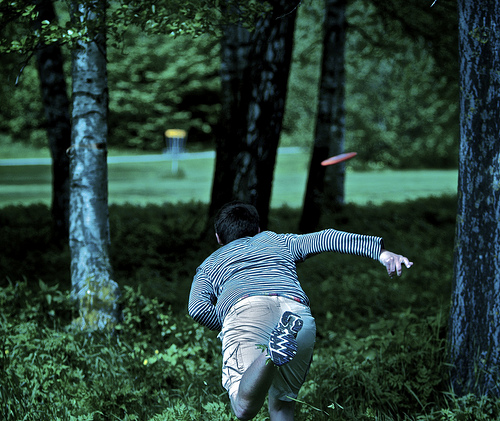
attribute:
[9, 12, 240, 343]
tree — bark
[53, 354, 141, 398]
plants — these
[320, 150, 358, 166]
frisbee — red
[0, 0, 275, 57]
leaves — hanging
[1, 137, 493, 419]
grass — patchy, green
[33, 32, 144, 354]
tree — bark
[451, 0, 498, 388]
tree — bark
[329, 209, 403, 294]
arms — out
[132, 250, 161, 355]
plants — these